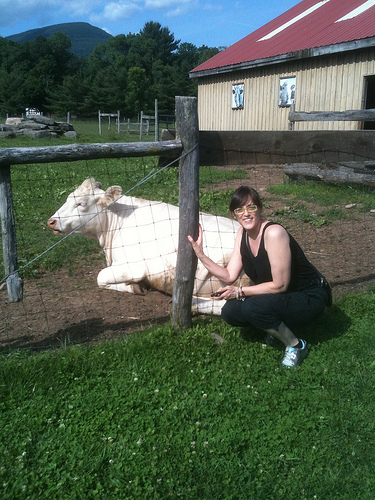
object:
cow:
[46, 176, 243, 314]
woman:
[187, 184, 334, 368]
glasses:
[233, 204, 258, 214]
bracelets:
[236, 287, 247, 302]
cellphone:
[210, 289, 226, 296]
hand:
[187, 221, 204, 258]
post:
[173, 96, 200, 333]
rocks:
[0, 106, 77, 140]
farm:
[3, 3, 367, 491]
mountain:
[1, 17, 124, 55]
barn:
[157, 0, 374, 168]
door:
[357, 75, 374, 130]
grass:
[15, 356, 362, 496]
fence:
[0, 94, 200, 351]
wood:
[152, 140, 184, 152]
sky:
[1, 4, 238, 20]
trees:
[115, 22, 169, 117]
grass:
[19, 167, 41, 262]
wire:
[20, 172, 113, 254]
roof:
[188, 0, 374, 80]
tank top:
[239, 221, 322, 293]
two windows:
[230, 75, 295, 110]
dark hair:
[233, 186, 259, 200]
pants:
[221, 278, 333, 332]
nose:
[47, 210, 57, 225]